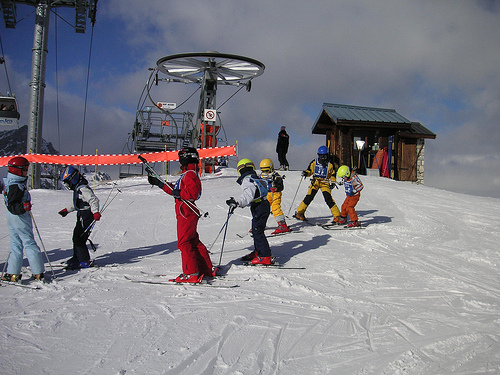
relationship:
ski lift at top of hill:
[116, 29, 258, 169] [293, 156, 431, 209]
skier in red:
[135, 141, 227, 289] [189, 211, 191, 228]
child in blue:
[3, 147, 59, 292] [20, 220, 30, 236]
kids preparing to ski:
[226, 138, 381, 279] [220, 200, 310, 275]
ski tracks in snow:
[320, 298, 403, 373] [415, 223, 474, 317]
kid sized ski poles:
[49, 154, 123, 283] [80, 179, 124, 249]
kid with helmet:
[49, 154, 123, 283] [59, 165, 83, 186]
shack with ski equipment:
[304, 93, 431, 186] [352, 131, 397, 177]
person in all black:
[268, 123, 294, 173] [281, 133, 287, 149]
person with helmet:
[268, 123, 294, 173] [279, 120, 290, 131]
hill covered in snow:
[293, 156, 431, 209] [415, 223, 474, 317]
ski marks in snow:
[247, 290, 362, 355] [415, 223, 474, 317]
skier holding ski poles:
[135, 136, 227, 289] [80, 179, 124, 249]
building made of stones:
[304, 93, 431, 186] [418, 144, 426, 166]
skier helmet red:
[135, 136, 227, 289] [189, 211, 191, 228]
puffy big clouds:
[456, 118, 494, 177] [345, 14, 494, 71]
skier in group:
[135, 141, 227, 289] [9, 129, 377, 296]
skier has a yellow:
[257, 153, 293, 235] [272, 196, 282, 210]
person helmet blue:
[268, 123, 294, 173] [20, 220, 30, 236]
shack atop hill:
[304, 100, 430, 186] [293, 156, 431, 209]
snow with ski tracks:
[415, 223, 474, 317] [320, 298, 403, 373]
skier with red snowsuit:
[135, 136, 227, 289] [160, 167, 215, 286]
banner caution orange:
[69, 141, 242, 163] [111, 154, 128, 162]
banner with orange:
[69, 141, 242, 163] [111, 154, 128, 162]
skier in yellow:
[257, 153, 293, 235] [272, 196, 282, 210]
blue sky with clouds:
[302, 8, 404, 39] [345, 14, 494, 71]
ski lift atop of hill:
[116, 29, 258, 169] [293, 156, 431, 209]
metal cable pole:
[34, 20, 41, 37] [34, 6, 48, 165]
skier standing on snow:
[135, 141, 227, 289] [415, 223, 474, 317]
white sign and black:
[203, 108, 220, 122] [281, 133, 287, 149]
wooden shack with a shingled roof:
[304, 93, 431, 186] [328, 104, 414, 129]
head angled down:
[58, 167, 86, 192] [59, 180, 72, 195]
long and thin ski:
[220, 207, 230, 270] [220, 200, 310, 275]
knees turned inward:
[302, 185, 337, 201] [312, 194, 325, 201]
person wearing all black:
[275, 123, 295, 170] [281, 133, 287, 149]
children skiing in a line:
[226, 138, 381, 279] [342, 230, 397, 253]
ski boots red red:
[249, 248, 277, 268] [189, 211, 191, 228]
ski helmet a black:
[174, 145, 198, 165] [281, 133, 287, 149]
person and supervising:
[268, 123, 294, 173] [281, 129, 285, 149]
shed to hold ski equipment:
[304, 93, 431, 186] [352, 131, 397, 177]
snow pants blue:
[253, 200, 276, 259] [20, 220, 30, 236]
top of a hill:
[297, 169, 306, 176] [0, 166, 499, 374]